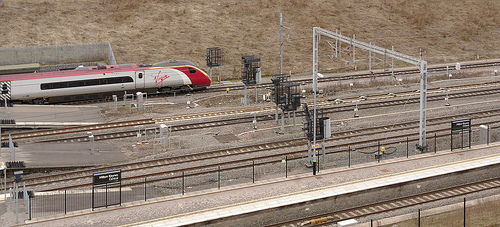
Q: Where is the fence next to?
A: Train tracks.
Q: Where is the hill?
A: Next to track.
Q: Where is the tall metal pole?
A: Covering the tracks.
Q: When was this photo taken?
A: The daytime.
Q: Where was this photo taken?
A: The outdoors.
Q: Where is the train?
A: On tracks.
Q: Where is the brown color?
A: The grass.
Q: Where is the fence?
A: In the front.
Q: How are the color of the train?
A: Red and gray.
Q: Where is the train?
A: On the tracks.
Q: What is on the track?
A: Train.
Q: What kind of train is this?
A: Bullet.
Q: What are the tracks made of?
A: Metal.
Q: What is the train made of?
A: Metal.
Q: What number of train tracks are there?
A: 5.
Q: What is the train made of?
A: Metal.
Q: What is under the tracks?
A: Gravel.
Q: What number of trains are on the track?
A: 1.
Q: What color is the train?
A: Red and silver.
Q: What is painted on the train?
A: Virgin.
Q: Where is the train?
A: On the tracks.